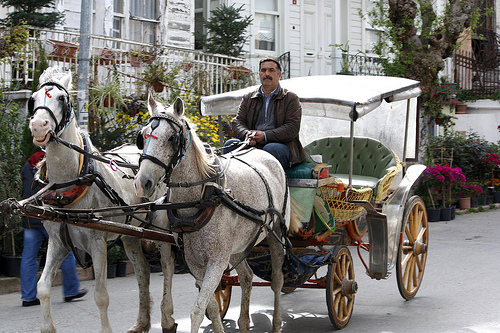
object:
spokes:
[402, 250, 416, 266]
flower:
[423, 162, 473, 207]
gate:
[15, 23, 308, 100]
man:
[222, 59, 302, 158]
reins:
[46, 98, 347, 213]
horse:
[28, 77, 136, 262]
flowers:
[157, 86, 255, 154]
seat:
[283, 123, 397, 199]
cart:
[192, 49, 443, 252]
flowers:
[412, 141, 480, 247]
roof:
[174, 60, 486, 154]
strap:
[43, 128, 268, 263]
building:
[40, 14, 498, 74]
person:
[2, 118, 105, 263]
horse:
[113, 98, 331, 263]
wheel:
[395, 200, 430, 299]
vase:
[428, 207, 441, 221]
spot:
[45, 91, 53, 100]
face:
[21, 79, 65, 150]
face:
[257, 59, 280, 86]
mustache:
[261, 75, 274, 82]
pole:
[64, 24, 108, 214]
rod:
[82, 187, 160, 223]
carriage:
[172, 39, 419, 255]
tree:
[394, 14, 452, 134]